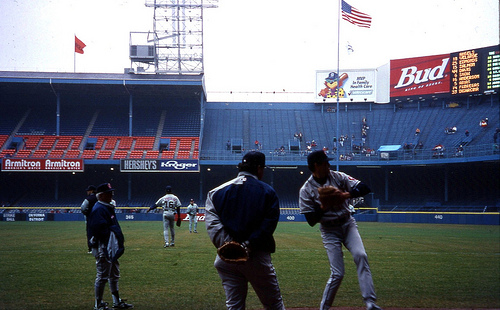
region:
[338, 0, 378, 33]
A red, white and blue American flag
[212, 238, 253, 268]
A brown leather baseball glove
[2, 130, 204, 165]
Red seats in the spectator stands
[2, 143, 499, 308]
People standing on a baseball field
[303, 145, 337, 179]
Hat on man's head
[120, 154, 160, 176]
"HERSHEYS" written on a sign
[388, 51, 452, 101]
Red sign with "Bud" written on it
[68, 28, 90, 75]
A flag is red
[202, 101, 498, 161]
Blue seats in the spectator stands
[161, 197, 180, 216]
Number 16 on back of a shirt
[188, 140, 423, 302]
the man is wearing a baseball uniform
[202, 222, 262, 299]
the man is wearing a baseball mitt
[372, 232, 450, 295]
the turf is green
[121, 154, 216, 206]
logos are in blue and white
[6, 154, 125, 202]
logos are in red and white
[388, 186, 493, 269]
the seats are blue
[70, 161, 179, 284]
the man is in a shadow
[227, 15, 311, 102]
the sky is cloudy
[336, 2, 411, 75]
the us flag is flying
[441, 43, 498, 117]
the scoreboard has names on it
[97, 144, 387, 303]
players standing on grass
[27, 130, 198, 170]
orange seats in field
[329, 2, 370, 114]
US flag in distance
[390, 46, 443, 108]
red and white sign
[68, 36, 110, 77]
red flag behind upper deck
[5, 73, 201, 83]
black awning on upper deck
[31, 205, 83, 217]
yellow foam on fence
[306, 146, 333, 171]
player has black cap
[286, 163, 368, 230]
player has grey shirt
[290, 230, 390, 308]
player has grey pants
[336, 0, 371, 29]
the American flag on a tall pole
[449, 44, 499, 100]
a lighted sign showing the line up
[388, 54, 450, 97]
a large, red Bud billboard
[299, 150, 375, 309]
a player with his hand in his glove ready to throw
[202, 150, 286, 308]
a player wearing a jacket with his glove behind him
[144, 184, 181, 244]
a player in uniform wearing number 16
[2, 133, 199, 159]
a block of red seats in the upper deck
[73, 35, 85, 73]
a red flag on a pole on the roof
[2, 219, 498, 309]
grass on the field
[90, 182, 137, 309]
an older man in uniform, but wearing a jacket on top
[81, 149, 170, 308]
A manager of a baseball team.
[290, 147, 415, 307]
A baseball player warming up.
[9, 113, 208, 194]
The upper deck seat in a baseball stadium.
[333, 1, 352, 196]
A flag pole in the baseball stadium.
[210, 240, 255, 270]
A baseball glove.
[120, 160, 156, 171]
A Hershey's banner along the upper deck.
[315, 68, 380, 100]
An advertisement on the baseball stadium.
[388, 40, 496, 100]
The Budweiser scoreboard for a baseball stadium.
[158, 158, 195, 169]
A Kroger advertisement sign.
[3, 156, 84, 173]
Two Armitron advertisement signs.